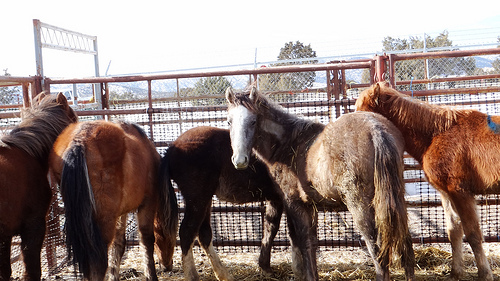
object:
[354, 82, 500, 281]
horse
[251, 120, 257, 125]
eye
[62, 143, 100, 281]
tail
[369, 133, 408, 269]
tail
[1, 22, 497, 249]
enclosure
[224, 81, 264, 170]
head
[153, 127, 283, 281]
horse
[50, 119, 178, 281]
horse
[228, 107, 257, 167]
face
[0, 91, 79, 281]
horses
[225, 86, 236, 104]
ear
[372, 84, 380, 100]
ear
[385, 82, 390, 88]
ear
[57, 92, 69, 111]
ear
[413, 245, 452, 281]
hay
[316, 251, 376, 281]
hay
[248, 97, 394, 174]
horses out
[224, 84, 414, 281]
horse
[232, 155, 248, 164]
nose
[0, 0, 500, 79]
sky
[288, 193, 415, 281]
legs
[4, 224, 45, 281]
legs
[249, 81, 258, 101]
ear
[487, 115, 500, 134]
print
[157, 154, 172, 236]
tail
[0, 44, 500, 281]
fence